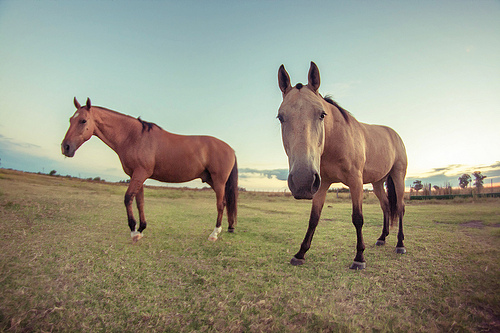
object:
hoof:
[208, 227, 223, 241]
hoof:
[348, 260, 367, 269]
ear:
[278, 63, 294, 96]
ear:
[308, 61, 321, 92]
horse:
[276, 59, 408, 270]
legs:
[295, 185, 331, 254]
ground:
[0, 276, 500, 333]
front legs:
[348, 185, 365, 258]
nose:
[288, 169, 322, 197]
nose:
[61, 144, 74, 155]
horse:
[60, 96, 239, 244]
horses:
[61, 62, 406, 270]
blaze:
[68, 100, 85, 123]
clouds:
[0, 135, 498, 191]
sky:
[2, 1, 498, 189]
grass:
[0, 167, 500, 333]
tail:
[225, 156, 239, 229]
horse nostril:
[311, 172, 322, 195]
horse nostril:
[287, 173, 296, 192]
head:
[61, 97, 94, 158]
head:
[275, 61, 327, 200]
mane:
[323, 94, 351, 126]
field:
[0, 168, 499, 333]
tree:
[472, 170, 487, 192]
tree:
[458, 173, 472, 189]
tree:
[412, 180, 424, 196]